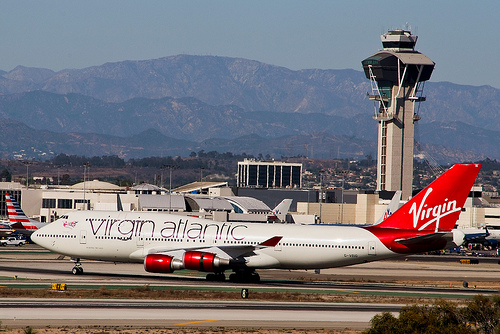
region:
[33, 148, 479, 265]
large white and red airplane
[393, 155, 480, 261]
red airplane tail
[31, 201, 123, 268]
nose of a airplane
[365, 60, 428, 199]
tower at a airport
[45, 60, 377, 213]
mountains behind a airport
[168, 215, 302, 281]
wing of a airplane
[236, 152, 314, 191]
white building behind airport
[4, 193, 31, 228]
striped airplane tail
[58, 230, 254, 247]
multiple windows on a airplane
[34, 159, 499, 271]
A Passenger flight waiting to start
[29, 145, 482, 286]
Aero plane belongs to Virgin Atlantic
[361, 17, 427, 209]
Watch tower of an airport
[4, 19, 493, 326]
A beautiful scene in the airport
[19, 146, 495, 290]
Passenger flight on the run way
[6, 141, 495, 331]
Different flights are waiting in the airport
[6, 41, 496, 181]
Big mountains scene shaping like a wave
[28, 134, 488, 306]
this is a plane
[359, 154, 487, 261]
red tail on plane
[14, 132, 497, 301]
a virgin atlantic plane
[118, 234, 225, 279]
red engines on plane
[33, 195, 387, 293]
white body of plain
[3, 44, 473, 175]
multiple mountains in background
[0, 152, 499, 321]
plane is on runway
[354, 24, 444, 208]
this is a tower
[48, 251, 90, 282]
landing gear on plane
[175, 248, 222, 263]
red engine of plane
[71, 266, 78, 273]
black wheel of plane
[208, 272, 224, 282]
black wheel of plane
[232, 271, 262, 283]
black wheel of planeblack wheel of plane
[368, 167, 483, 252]
red tail of plane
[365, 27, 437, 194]
tall tower by plane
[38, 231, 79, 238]
windows on plane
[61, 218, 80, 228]
red logo on plane front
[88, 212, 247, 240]
writing on side of plane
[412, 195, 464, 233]
The word Virgin on the plane.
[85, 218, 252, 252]
The words virgin atlantic.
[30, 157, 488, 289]
The virgin atlantic plane.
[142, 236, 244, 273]
The left plane wing.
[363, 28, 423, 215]
A tall watch tower.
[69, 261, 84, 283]
The planes front wheels.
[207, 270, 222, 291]
The planes left wheels.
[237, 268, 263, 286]
The planes right wheels.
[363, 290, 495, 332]
The patch of grass.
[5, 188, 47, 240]
Red, white and blue design on plane.